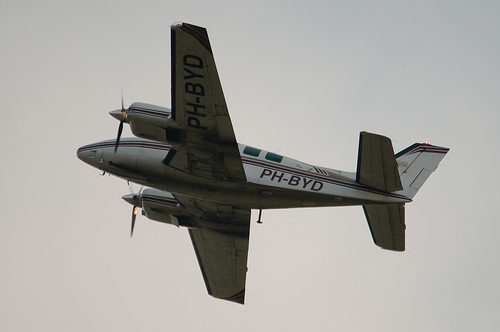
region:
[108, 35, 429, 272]
small personal plane in the sky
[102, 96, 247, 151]
propeller engine on wing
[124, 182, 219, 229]
propeller engine on wing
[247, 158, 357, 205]
identification number of plane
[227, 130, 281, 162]
glass windows on side of plane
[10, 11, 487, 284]
gray overcast sky around plane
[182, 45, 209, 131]
identification number of plane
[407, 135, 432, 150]
red light on tail of plane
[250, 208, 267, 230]
small wire hanging from plane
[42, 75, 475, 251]
A big white plane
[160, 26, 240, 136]
A big white plane wing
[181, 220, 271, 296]
A big white plane wing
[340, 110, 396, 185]
A big white plane wing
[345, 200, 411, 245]
A big white plane wing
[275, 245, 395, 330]
A grey sky background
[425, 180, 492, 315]
A grey sky background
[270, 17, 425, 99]
A grey sky background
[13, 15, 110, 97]
A grey sky background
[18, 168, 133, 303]
A grey sky background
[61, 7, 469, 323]
a plane travel in a cloudy sky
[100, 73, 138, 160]
propeller on left side of plane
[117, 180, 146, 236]
propeller on right side of plane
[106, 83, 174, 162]
an engine above a wing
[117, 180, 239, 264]
an engine above a wing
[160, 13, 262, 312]
the wings of plane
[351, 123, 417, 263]
horizontal stabilizer of plane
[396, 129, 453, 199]
a vertical stabilizer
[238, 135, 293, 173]
side windows of plane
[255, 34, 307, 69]
this is the sky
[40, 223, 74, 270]
the sky has clouds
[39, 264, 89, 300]
the clouds are white in color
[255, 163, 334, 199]
these are some writings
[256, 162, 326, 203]
the writings are in bold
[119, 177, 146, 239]
this is a propeller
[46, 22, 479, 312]
this is an airplane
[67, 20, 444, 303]
the airplane is small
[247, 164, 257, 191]
the airplane is white in color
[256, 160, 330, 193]
lettering on the side of plane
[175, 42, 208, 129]
lettering onthe plane's wing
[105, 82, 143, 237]
two propellors on the plane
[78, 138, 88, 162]
nose of the airplane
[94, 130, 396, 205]
dark red lines on the airplane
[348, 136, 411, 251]
wings on the tail of the airplane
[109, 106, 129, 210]
noses on the propellors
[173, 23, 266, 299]
wings on the side of the airplane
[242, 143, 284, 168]
two windows on the side of the plane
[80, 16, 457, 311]
airplane flying through the sky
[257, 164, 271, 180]
a black capital letter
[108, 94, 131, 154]
an airplane propeller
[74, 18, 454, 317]
a small airplane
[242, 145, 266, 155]
a small airplane window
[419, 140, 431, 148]
a small red plane light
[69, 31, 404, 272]
a plane in the air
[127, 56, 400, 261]
a plane in the air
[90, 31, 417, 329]
a plane in the air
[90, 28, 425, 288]
a plane in the air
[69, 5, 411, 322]
a plane in the air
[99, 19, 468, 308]
a plane in the air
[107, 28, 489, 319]
a plane in the air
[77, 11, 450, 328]
a plane in the air